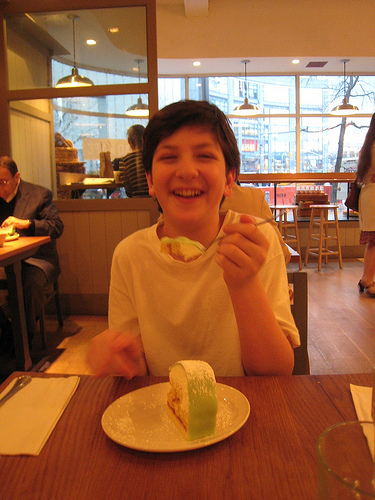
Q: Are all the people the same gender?
A: No, they are both male and female.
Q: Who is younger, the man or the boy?
A: The boy is younger than the man.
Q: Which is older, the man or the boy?
A: The man is older than the boy.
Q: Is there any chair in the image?
A: Yes, there is a chair.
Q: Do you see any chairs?
A: Yes, there is a chair.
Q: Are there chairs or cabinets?
A: Yes, there is a chair.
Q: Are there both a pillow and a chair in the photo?
A: No, there is a chair but no pillows.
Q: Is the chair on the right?
A: Yes, the chair is on the right of the image.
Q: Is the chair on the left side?
A: No, the chair is on the right of the image.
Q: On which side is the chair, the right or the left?
A: The chair is on the right of the image.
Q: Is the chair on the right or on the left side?
A: The chair is on the right of the image.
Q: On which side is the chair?
A: The chair is on the right of the image.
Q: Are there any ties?
A: No, there are no ties.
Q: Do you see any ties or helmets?
A: No, there are no ties or helmets.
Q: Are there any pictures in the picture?
A: No, there are no pictures.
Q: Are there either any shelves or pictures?
A: No, there are no pictures or shelves.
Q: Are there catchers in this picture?
A: No, there are no catchers.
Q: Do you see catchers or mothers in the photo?
A: No, there are no catchers or mothers.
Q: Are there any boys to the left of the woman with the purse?
A: Yes, there is a boy to the left of the woman.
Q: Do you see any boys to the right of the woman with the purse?
A: No, the boy is to the left of the woman.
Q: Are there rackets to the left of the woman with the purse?
A: No, there is a boy to the left of the woman.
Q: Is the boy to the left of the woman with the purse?
A: Yes, the boy is to the left of the woman.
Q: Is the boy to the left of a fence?
A: No, the boy is to the left of the woman.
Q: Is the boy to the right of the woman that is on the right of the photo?
A: No, the boy is to the left of the woman.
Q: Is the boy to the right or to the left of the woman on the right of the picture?
A: The boy is to the left of the woman.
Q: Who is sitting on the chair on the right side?
A: The boy is sitting on the chair.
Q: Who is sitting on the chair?
A: The boy is sitting on the chair.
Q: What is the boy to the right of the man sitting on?
A: The boy is sitting on the chair.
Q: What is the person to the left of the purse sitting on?
A: The boy is sitting on the chair.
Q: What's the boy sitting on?
A: The boy is sitting on the chair.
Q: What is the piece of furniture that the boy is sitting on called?
A: The piece of furniture is a chair.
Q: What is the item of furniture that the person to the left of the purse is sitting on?
A: The piece of furniture is a chair.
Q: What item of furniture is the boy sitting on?
A: The boy is sitting on the chair.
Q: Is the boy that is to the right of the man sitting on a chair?
A: Yes, the boy is sitting on a chair.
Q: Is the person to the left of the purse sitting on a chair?
A: Yes, the boy is sitting on a chair.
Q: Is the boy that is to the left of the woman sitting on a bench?
A: No, the boy is sitting on a chair.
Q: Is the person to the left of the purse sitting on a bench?
A: No, the boy is sitting on a chair.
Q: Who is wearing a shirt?
A: The boy is wearing a shirt.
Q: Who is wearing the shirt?
A: The boy is wearing a shirt.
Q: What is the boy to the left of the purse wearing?
A: The boy is wearing a shirt.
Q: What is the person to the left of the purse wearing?
A: The boy is wearing a shirt.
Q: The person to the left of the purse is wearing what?
A: The boy is wearing a shirt.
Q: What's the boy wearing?
A: The boy is wearing a shirt.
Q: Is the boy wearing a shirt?
A: Yes, the boy is wearing a shirt.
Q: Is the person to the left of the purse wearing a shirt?
A: Yes, the boy is wearing a shirt.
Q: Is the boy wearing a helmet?
A: No, the boy is wearing a shirt.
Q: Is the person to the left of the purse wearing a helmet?
A: No, the boy is wearing a shirt.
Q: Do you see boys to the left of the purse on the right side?
A: Yes, there is a boy to the left of the purse.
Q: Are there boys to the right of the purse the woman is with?
A: No, the boy is to the left of the purse.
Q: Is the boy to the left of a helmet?
A: No, the boy is to the left of the purse.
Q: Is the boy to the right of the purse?
A: No, the boy is to the left of the purse.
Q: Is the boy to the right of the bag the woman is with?
A: No, the boy is to the left of the purse.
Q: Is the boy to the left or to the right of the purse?
A: The boy is to the left of the purse.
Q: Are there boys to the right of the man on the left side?
A: Yes, there is a boy to the right of the man.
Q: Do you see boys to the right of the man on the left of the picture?
A: Yes, there is a boy to the right of the man.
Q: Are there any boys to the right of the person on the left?
A: Yes, there is a boy to the right of the man.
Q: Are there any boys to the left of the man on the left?
A: No, the boy is to the right of the man.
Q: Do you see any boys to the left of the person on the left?
A: No, the boy is to the right of the man.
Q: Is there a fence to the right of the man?
A: No, there is a boy to the right of the man.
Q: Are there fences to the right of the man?
A: No, there is a boy to the right of the man.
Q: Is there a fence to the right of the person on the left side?
A: No, there is a boy to the right of the man.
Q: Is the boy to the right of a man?
A: Yes, the boy is to the right of a man.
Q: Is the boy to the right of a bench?
A: No, the boy is to the right of a man.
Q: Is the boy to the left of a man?
A: No, the boy is to the right of a man.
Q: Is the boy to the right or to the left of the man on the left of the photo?
A: The boy is to the right of the man.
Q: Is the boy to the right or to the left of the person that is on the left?
A: The boy is to the right of the man.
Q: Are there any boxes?
A: No, there are no boxes.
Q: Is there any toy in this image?
A: No, there are no toys.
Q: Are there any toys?
A: No, there are no toys.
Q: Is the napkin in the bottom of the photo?
A: Yes, the napkin is in the bottom of the image.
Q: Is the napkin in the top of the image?
A: No, the napkin is in the bottom of the image.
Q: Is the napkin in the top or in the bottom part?
A: The napkin is in the bottom of the image.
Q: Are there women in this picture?
A: Yes, there is a woman.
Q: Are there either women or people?
A: Yes, there is a woman.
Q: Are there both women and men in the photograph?
A: Yes, there are both a woman and a man.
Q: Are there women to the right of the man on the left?
A: Yes, there is a woman to the right of the man.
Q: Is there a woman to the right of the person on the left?
A: Yes, there is a woman to the right of the man.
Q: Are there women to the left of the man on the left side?
A: No, the woman is to the right of the man.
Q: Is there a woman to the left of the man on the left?
A: No, the woman is to the right of the man.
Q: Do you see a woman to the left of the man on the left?
A: No, the woman is to the right of the man.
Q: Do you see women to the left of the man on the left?
A: No, the woman is to the right of the man.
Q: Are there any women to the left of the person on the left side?
A: No, the woman is to the right of the man.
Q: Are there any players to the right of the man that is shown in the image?
A: No, there is a woman to the right of the man.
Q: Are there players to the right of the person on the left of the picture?
A: No, there is a woman to the right of the man.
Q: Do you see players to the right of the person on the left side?
A: No, there is a woman to the right of the man.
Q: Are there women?
A: Yes, there is a woman.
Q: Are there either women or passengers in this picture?
A: Yes, there is a woman.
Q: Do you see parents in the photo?
A: No, there are no parents.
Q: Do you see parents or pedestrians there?
A: No, there are no parents or pedestrians.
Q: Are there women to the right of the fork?
A: Yes, there is a woman to the right of the fork.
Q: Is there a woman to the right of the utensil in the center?
A: Yes, there is a woman to the right of the fork.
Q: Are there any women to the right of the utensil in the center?
A: Yes, there is a woman to the right of the fork.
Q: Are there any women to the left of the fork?
A: No, the woman is to the right of the fork.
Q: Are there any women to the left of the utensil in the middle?
A: No, the woman is to the right of the fork.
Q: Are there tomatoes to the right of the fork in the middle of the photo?
A: No, there is a woman to the right of the fork.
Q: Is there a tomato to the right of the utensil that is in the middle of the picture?
A: No, there is a woman to the right of the fork.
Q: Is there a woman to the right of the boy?
A: Yes, there is a woman to the right of the boy.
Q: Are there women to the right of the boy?
A: Yes, there is a woman to the right of the boy.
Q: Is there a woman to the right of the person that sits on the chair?
A: Yes, there is a woman to the right of the boy.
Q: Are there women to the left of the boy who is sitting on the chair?
A: No, the woman is to the right of the boy.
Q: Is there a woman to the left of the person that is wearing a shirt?
A: No, the woman is to the right of the boy.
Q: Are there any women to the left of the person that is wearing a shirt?
A: No, the woman is to the right of the boy.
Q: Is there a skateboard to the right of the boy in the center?
A: No, there is a woman to the right of the boy.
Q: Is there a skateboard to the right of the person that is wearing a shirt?
A: No, there is a woman to the right of the boy.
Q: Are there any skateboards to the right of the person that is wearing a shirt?
A: No, there is a woman to the right of the boy.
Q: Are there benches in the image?
A: No, there are no benches.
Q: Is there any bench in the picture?
A: No, there are no benches.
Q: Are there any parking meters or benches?
A: No, there are no benches or parking meters.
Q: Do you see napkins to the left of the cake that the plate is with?
A: Yes, there is a napkin to the left of the cake.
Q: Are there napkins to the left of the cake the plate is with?
A: Yes, there is a napkin to the left of the cake.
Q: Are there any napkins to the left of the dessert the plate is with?
A: Yes, there is a napkin to the left of the cake.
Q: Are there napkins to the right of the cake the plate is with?
A: No, the napkin is to the left of the cake.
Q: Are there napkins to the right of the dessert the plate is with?
A: No, the napkin is to the left of the cake.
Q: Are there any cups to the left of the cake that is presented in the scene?
A: No, there is a napkin to the left of the cake.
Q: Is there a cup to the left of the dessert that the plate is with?
A: No, there is a napkin to the left of the cake.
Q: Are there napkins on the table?
A: Yes, there is a napkin on the table.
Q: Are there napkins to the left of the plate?
A: Yes, there is a napkin to the left of the plate.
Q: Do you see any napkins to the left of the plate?
A: Yes, there is a napkin to the left of the plate.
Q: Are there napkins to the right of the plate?
A: No, the napkin is to the left of the plate.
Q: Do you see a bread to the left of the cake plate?
A: No, there is a napkin to the left of the plate.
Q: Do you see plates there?
A: Yes, there is a plate.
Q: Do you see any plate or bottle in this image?
A: Yes, there is a plate.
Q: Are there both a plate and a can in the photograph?
A: No, there is a plate but no cans.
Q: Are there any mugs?
A: No, there are no mugs.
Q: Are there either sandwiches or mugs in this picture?
A: No, there are no mugs or sandwiches.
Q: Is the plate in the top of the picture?
A: No, the plate is in the bottom of the image.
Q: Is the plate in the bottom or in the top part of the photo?
A: The plate is in the bottom of the image.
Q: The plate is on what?
A: The plate is on the table.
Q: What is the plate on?
A: The plate is on the table.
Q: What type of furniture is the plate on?
A: The plate is on the table.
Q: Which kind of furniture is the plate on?
A: The plate is on the table.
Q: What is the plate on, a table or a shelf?
A: The plate is on a table.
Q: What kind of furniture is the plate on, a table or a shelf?
A: The plate is on a table.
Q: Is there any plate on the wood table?
A: Yes, there is a plate on the table.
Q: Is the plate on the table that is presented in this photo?
A: Yes, the plate is on the table.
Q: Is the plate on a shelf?
A: No, the plate is on the table.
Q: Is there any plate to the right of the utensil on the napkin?
A: Yes, there is a plate to the right of the utensil.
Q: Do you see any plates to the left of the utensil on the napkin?
A: No, the plate is to the right of the utensil.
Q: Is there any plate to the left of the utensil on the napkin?
A: No, the plate is to the right of the utensil.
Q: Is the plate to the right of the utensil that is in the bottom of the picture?
A: Yes, the plate is to the right of the utensil.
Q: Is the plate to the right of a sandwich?
A: No, the plate is to the right of the utensil.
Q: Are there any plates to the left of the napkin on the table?
A: No, the plate is to the right of the napkin.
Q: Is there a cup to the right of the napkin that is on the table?
A: No, there is a plate to the right of the napkin.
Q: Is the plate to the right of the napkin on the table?
A: Yes, the plate is to the right of the napkin.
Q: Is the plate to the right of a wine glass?
A: No, the plate is to the right of the napkin.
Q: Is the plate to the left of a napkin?
A: No, the plate is to the right of a napkin.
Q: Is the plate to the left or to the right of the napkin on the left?
A: The plate is to the right of the napkin.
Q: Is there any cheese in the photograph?
A: No, there is no cheese.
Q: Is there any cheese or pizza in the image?
A: No, there are no cheese or pizzas.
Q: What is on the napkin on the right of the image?
A: The utensil is on the napkin.